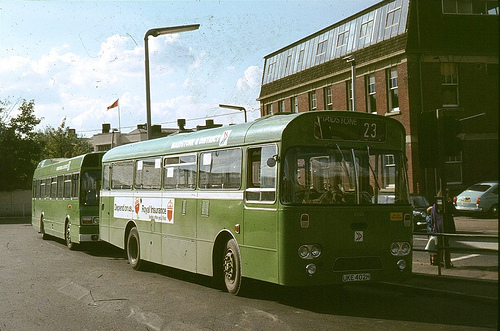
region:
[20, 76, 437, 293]
old green city bus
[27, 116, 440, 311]
two green school buses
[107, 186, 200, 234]
white and red banner on side of bus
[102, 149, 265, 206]
windows of bus are open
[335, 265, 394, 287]
license plate on front of bus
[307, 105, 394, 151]
destination and number of bus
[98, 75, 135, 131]
flag waving in the distance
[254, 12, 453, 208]
brick building with several windows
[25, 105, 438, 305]
two buses parked next to each other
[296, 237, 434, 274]
headlights on front of bus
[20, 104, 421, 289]
two old buses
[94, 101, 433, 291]
one green transport bus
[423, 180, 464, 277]
a person standing on the sidewalk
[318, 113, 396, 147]
number on the bus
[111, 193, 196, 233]
a sign on the side of the bus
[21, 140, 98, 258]
one green transport bus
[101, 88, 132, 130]
a flag flowing in the wind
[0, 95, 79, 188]
green leafy trees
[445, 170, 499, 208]
a little blue car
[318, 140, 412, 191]
window wipers on bus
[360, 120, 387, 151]
Number 23 on front of bus.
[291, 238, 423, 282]
Lights on front of bus.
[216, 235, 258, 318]
Black wheel on bus.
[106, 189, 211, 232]
White sign on side of bus.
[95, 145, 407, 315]
Green bus on side of road.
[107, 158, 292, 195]
Large windows on side of bus.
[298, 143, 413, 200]
Large windshield on front of bus.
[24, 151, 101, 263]
Green bus on side of road.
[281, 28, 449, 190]
Large brick building in background.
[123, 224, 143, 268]
Black wheel on bus.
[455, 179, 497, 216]
Blue car parked on side of road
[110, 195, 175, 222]
Banner displayed on side of green bus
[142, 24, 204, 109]
Street light mounted to pole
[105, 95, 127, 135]
Flag flying over buildings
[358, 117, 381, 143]
Number on front of green bus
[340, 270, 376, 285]
Front license plate on green bus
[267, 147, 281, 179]
Rear view mirror mounted on outer passenger side of green bus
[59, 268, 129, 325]
Design in concrete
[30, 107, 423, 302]
Green buses parked next to road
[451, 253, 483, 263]
White line painted on road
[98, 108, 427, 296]
Green bus parked in lot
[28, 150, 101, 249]
Green bus parked behind green bus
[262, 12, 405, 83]
Windows on top floor of building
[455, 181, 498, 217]
White car parked off the street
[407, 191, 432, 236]
Black car parked on the street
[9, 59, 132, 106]
Blue sky with white clouds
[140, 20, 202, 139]
Street light above the bus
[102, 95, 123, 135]
Red flag on top of building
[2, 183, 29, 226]
White fence in background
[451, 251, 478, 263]
White line on street